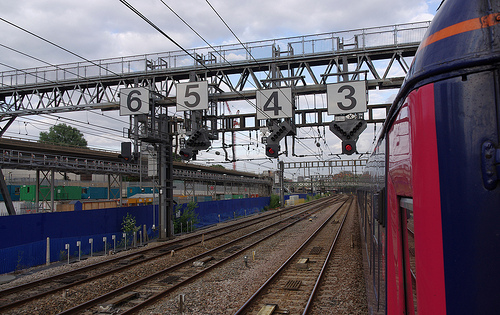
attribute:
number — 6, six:
[119, 90, 152, 118]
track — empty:
[6, 184, 362, 312]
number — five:
[177, 81, 212, 113]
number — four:
[260, 89, 290, 122]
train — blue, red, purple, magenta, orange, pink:
[346, 0, 493, 315]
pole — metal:
[150, 121, 178, 239]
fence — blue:
[7, 189, 272, 263]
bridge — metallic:
[12, 132, 288, 188]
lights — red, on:
[180, 143, 359, 158]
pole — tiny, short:
[62, 241, 75, 263]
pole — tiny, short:
[74, 239, 86, 265]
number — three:
[323, 81, 368, 116]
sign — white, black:
[323, 76, 379, 126]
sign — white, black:
[251, 86, 294, 121]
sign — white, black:
[172, 80, 212, 116]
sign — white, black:
[118, 87, 153, 116]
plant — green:
[117, 213, 144, 253]